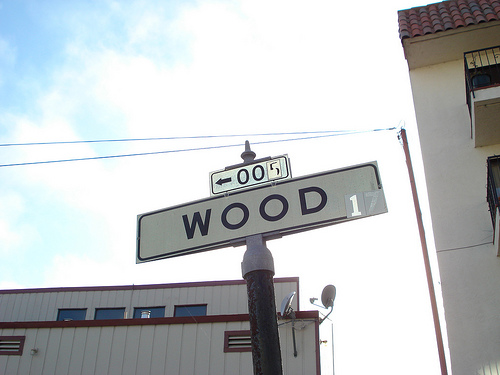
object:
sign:
[133, 160, 387, 265]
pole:
[241, 269, 285, 375]